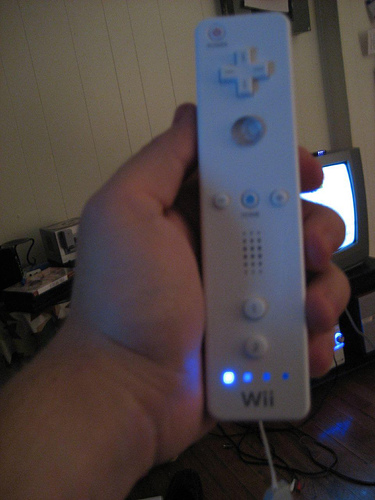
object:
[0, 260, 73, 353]
book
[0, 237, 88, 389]
shelf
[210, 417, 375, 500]
cords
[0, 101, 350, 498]
someone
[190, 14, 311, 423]
controller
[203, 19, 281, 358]
button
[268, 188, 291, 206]
button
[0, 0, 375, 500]
picture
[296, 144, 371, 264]
television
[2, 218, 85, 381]
table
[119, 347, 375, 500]
floor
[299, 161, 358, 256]
light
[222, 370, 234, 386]
lights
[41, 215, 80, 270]
box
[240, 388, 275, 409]
graphic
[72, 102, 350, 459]
hand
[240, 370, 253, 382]
light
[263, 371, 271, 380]
light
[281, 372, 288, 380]
light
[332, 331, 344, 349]
light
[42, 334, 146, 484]
wrist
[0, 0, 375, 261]
wall